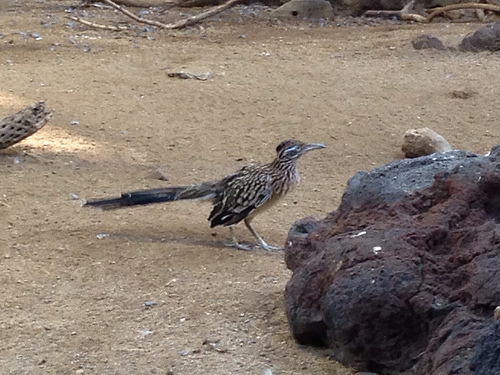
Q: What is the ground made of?
A: Dirt and gravel.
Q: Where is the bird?
A: On dry land.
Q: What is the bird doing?
A: It is hunting.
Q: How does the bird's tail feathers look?
A: They are long.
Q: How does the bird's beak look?
A: It is sharp.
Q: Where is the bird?
A: Standing on the sand.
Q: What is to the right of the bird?
A: A rock.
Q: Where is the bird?
A: On the ground.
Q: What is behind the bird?
A: A long tail feather.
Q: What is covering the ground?
A: Sand.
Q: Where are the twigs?
A: Behind the bird.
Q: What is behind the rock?
A: Another rock.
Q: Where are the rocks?
A: On the ground.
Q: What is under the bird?
A: The ground.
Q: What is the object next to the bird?
A: A brown and gray rock.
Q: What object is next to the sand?
A: A brown and gray rock.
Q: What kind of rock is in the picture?
A: A brown and gray rock.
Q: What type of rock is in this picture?
A: A large reddish desert rock.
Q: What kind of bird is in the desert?
A: A roadrunner bird.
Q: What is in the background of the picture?
A: Several dead tree branches.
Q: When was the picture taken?
A: Daytime.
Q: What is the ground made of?
A: Dirt.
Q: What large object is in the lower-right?
A: Rock.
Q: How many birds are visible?
A: One.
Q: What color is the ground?
A: Brown.